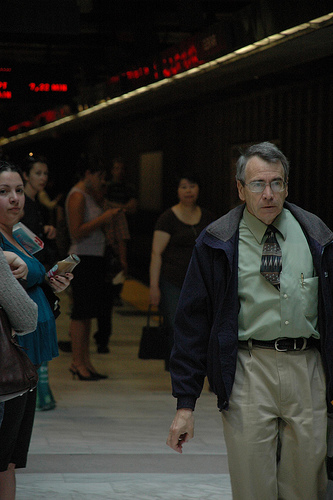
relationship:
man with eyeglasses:
[211, 147, 321, 254] [240, 179, 293, 196]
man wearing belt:
[211, 147, 321, 254] [240, 332, 331, 358]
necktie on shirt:
[261, 224, 289, 298] [239, 216, 318, 341]